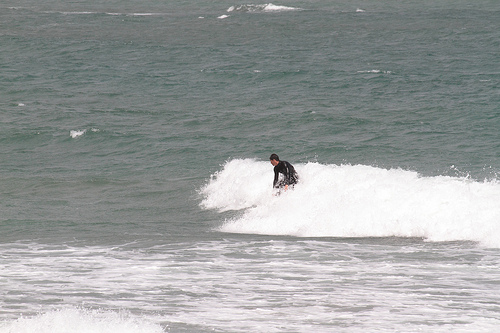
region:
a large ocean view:
[0, 0, 498, 332]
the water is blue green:
[2, 1, 498, 239]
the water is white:
[1, 156, 498, 331]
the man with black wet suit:
[265, 151, 300, 196]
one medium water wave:
[195, 147, 497, 242]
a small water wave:
[212, 0, 311, 23]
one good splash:
[2, 295, 167, 332]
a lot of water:
[1, 0, 499, 332]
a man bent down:
[260, 148, 300, 198]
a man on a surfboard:
[268, 148, 299, 196]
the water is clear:
[217, 260, 242, 287]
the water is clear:
[215, 267, 241, 312]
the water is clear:
[198, 245, 230, 297]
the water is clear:
[208, 263, 251, 327]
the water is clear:
[189, 308, 203, 326]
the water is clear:
[233, 274, 261, 308]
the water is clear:
[250, 285, 273, 316]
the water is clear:
[265, 287, 288, 331]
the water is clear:
[263, 280, 280, 312]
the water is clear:
[261, 298, 288, 318]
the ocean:
[1, 5, 481, 310]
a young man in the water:
[265, 145, 300, 200]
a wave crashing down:
[230, 165, 485, 245]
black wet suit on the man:
[260, 155, 295, 185]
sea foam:
[40, 230, 490, 330]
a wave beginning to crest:
[206, 0, 291, 15]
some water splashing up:
[1, 302, 169, 330]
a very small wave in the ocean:
[48, 116, 123, 156]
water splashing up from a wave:
[432, 152, 499, 181]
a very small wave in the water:
[351, 66, 407, 74]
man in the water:
[225, 120, 345, 241]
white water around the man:
[338, 141, 415, 222]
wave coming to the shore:
[331, 142, 441, 234]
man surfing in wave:
[241, 145, 312, 217]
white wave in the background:
[248, 6, 303, 32]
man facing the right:
[253, 113, 315, 222]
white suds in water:
[164, 231, 257, 314]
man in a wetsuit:
[244, 147, 309, 213]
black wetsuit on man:
[273, 161, 308, 185]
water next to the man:
[54, 126, 147, 216]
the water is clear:
[250, 288, 261, 303]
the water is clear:
[287, 273, 302, 297]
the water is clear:
[267, 294, 282, 321]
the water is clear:
[247, 271, 269, 311]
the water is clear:
[280, 282, 297, 321]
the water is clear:
[288, 303, 303, 330]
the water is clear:
[283, 311, 297, 331]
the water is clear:
[279, 295, 291, 317]